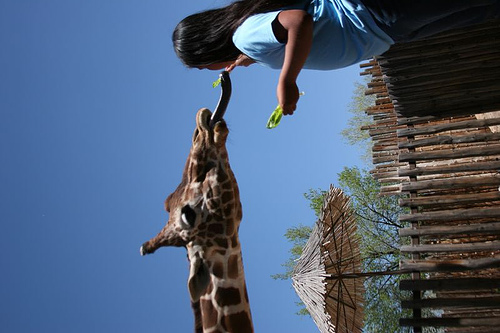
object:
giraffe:
[139, 106, 243, 330]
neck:
[179, 239, 256, 330]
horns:
[141, 233, 168, 256]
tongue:
[206, 70, 238, 127]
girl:
[173, 4, 498, 115]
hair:
[172, 0, 248, 69]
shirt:
[232, 0, 396, 72]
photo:
[1, 2, 495, 332]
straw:
[287, 189, 366, 333]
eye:
[179, 206, 197, 230]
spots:
[201, 286, 241, 327]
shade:
[387, 35, 496, 127]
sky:
[7, 3, 391, 333]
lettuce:
[265, 92, 306, 130]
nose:
[193, 129, 203, 142]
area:
[359, 0, 500, 331]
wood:
[358, 21, 497, 333]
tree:
[271, 71, 434, 333]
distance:
[253, 95, 469, 328]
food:
[212, 74, 225, 88]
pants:
[362, 4, 499, 37]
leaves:
[344, 169, 375, 205]